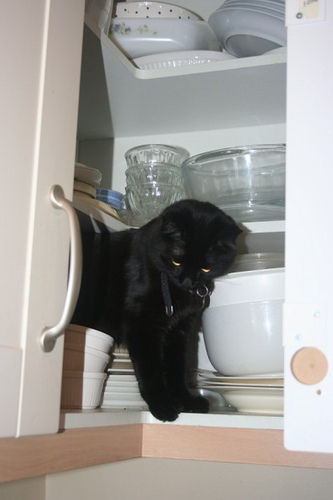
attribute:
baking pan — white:
[110, 16, 218, 56]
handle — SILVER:
[48, 184, 82, 351]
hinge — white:
[289, 341, 320, 386]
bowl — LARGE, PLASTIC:
[177, 142, 283, 226]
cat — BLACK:
[78, 195, 246, 430]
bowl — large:
[176, 122, 295, 221]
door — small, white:
[0, 0, 84, 437]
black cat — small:
[70, 199, 245, 421]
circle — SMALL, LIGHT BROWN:
[279, 337, 331, 399]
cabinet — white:
[17, 6, 325, 471]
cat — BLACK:
[58, 193, 252, 427]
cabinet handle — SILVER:
[44, 183, 84, 353]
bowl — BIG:
[190, 142, 279, 207]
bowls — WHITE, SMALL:
[204, 7, 256, 43]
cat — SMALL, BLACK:
[68, 197, 244, 422]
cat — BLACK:
[78, 204, 271, 420]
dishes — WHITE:
[67, 327, 166, 409]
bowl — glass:
[174, 141, 287, 219]